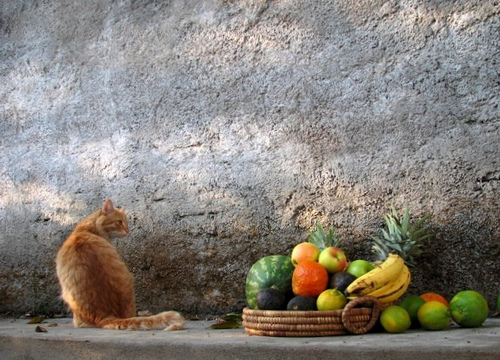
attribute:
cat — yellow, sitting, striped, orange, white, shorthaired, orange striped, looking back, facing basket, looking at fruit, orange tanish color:
[53, 198, 185, 334]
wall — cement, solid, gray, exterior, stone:
[2, 1, 500, 317]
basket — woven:
[239, 298, 382, 338]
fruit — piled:
[244, 203, 433, 309]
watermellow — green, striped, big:
[243, 253, 294, 310]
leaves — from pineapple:
[371, 200, 435, 269]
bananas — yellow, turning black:
[347, 251, 412, 305]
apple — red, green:
[319, 246, 348, 273]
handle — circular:
[340, 294, 380, 335]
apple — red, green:
[290, 242, 319, 271]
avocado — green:
[254, 286, 288, 311]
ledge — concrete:
[1, 315, 500, 358]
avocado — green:
[284, 295, 320, 314]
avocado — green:
[330, 270, 355, 294]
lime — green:
[449, 289, 489, 328]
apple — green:
[346, 257, 374, 280]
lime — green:
[418, 300, 454, 331]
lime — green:
[399, 294, 428, 329]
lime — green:
[380, 304, 411, 333]